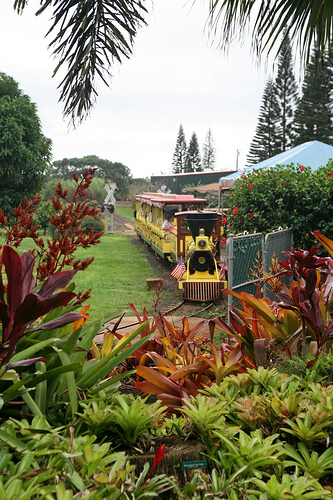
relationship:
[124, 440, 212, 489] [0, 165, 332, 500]
tree stump in middle of plants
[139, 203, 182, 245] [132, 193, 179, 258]
tourists are on right side of train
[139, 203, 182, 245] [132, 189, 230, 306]
tourists on right side of train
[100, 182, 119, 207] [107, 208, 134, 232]
crossing sign beside tracks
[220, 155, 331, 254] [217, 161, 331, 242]
tree top blooming red flowers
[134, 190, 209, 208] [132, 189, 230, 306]
roof on top of train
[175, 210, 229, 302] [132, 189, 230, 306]
engine of small passenger trai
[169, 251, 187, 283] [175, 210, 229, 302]
american flag on train engine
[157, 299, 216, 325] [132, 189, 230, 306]
part of track in front of train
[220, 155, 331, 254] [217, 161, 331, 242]
green bush has red flowers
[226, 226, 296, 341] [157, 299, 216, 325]
chain link gate near train tracks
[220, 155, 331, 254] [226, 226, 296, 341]
colorful plant behind gate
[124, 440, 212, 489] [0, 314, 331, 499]
tree stump surrounded by green plants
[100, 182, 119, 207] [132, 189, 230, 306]
crossing sign by train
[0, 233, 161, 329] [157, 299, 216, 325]
grass by tracks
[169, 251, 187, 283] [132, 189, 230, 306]
american flag hanging from train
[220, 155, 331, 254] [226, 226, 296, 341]
rosebush behind fence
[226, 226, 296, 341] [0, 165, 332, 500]
chain link fence separates plants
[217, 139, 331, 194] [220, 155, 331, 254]
awning behind rosebush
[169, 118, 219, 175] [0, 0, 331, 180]
evergreen trees are in background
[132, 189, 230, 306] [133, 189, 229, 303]
train on train